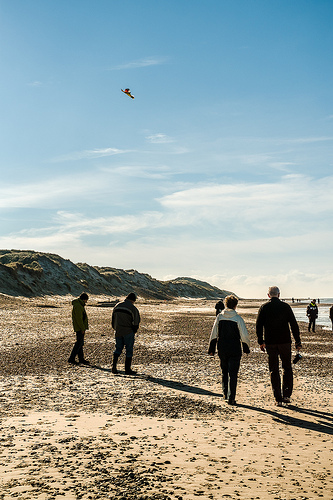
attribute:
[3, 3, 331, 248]
sky — blue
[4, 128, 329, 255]
these — clouds, white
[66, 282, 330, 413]
people — walking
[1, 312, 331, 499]
beach — brown, sandy, white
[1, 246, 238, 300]
hill — small, brown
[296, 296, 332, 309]
water — blue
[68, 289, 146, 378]
these — men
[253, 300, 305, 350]
sweater — black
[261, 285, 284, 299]
hair — grey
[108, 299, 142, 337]
jacket — pictured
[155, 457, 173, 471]
rocks — brown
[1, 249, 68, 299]
dunes — large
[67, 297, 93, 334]
jacket — grey